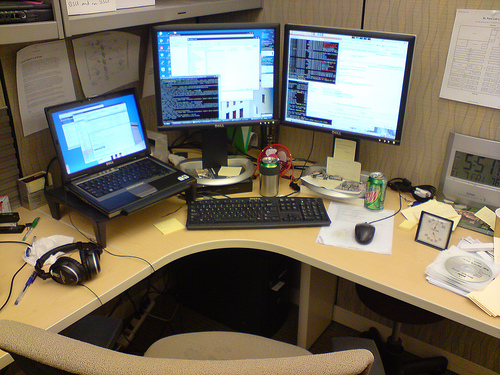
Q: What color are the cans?
A: Green.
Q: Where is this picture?
A: Office.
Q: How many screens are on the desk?
A: Three.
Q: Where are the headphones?
A: On the desk.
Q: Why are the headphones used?
A: To listen to audio.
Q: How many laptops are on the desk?
A: One.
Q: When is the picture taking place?
A: Five fifty one.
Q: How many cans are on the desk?
A: Two.